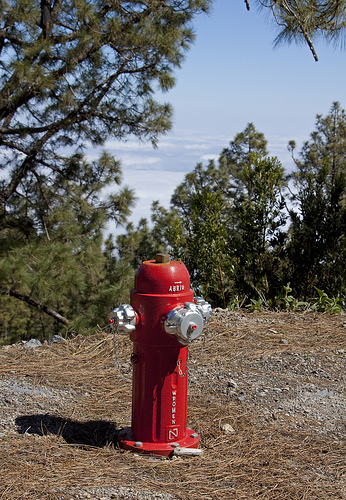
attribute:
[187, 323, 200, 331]
knob — silver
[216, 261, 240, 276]
leaves — green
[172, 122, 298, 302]
tree — brown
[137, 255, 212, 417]
hydrant — fire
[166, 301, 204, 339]
knob — silver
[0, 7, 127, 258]
tree — brown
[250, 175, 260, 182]
leaves — green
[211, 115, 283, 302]
tree — brown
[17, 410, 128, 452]
shadow — black